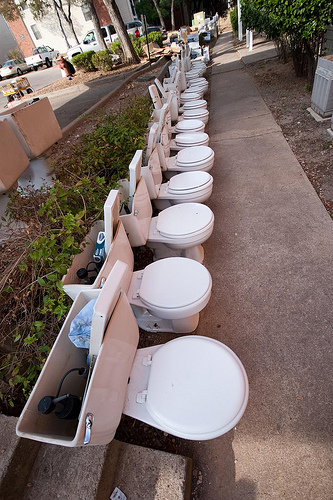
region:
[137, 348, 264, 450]
seat cover is down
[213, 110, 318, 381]
the sidewalk is paved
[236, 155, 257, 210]
Part of the sidewalk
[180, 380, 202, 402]
Part of the toilet seat cover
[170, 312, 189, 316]
Part of the toilet seat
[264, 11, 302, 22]
Part of the green tree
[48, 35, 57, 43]
Part of the building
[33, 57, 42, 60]
Part of the truck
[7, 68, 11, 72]
Part of the car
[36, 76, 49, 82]
Part of the street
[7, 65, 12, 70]
A red light in distance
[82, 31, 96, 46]
A window on the truck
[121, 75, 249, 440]
row of white toilets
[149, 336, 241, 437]
top of first toilet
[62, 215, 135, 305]
water tank of the second toilet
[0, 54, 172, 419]
plants in back of the toilets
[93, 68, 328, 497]
concrete the toilets are setting on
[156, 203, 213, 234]
third toilet's top of the seat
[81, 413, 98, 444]
handle on the water tank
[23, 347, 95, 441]
inside of the first toilet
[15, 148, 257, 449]
four toilets next to each other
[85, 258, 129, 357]
first toilet's water tanks' top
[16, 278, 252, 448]
White toilet on the concrete.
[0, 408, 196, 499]
concrete step on the ground.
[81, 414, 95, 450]
Silver colored flush handle.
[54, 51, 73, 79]
Fire hydrant in the background.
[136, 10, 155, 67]
Street sign in the background.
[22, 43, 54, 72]
Parked white truck.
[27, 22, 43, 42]
Window in the building.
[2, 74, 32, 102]
Wagon on the street.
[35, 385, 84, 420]
Plumbing in the toilet.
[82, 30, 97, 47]
Truck in the window.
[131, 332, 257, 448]
this is a toilet bowl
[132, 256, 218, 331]
this is a toilet bowl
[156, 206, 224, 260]
this is a toilet bowl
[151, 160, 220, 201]
this is a toilet bowl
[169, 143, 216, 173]
this is a toilet bowl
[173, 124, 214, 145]
this is a toilet bowl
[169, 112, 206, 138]
this is a toilet bowl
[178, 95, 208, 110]
this is a toilet bowl